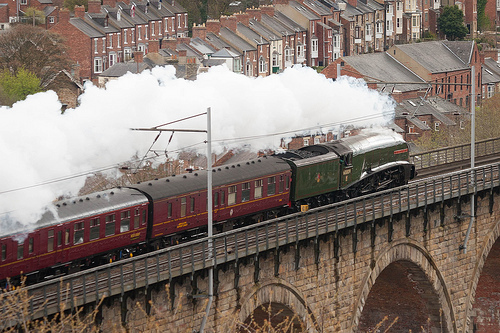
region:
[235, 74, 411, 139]
large section of white smoke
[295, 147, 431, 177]
green car on train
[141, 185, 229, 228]
tall windows on side of train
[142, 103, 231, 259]
tall silver pole on bridge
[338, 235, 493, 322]
large brick archway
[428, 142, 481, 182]
black train tracks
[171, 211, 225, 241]
yellow words on the side of train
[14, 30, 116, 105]
large over turned green tree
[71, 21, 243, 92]
large red apartment building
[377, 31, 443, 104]
gray roof on apartment building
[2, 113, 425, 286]
Green and red train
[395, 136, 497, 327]
Train bridge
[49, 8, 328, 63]
Housing overlooking the train bridge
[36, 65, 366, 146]
Steam from the train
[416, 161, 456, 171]
Train track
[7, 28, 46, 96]
Trees tucked beside the houses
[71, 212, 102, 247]
Train windows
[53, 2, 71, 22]
A brick chimney on the houses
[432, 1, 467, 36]
A healthy tree in front of the houses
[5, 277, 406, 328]
Weeds in the forground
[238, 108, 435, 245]
Green train engine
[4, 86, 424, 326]
Train with 3 cars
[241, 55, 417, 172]
smoke coming from train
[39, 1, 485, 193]
Many houses behind train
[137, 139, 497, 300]
Train going over bridge.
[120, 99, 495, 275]
Cables running by train tracks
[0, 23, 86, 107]
Trees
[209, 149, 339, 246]
Some train window shades are closed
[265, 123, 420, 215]
Coal inside train engine car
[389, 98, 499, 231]
Railings beside train tracks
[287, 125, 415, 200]
green train engine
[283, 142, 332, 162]
coal supply for train engine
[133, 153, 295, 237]
first dark red passenger car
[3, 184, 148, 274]
second dark red passenger car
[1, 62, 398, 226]
smoke from train locomotive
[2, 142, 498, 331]
railroad bridge over river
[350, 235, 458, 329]
brick arch of bridge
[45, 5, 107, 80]
brick rowhouse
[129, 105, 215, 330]
electrical pole attached to bridge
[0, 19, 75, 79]
tree just starting to leaf out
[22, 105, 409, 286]
train on the tracks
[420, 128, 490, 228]
tracks on a bridge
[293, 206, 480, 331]
bridge below tracks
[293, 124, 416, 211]
Green front of the train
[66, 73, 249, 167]
snow next to train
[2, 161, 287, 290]
windows on the train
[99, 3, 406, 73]
buildings next to train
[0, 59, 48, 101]
tree next to houses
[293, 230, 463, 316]
brown bridge below train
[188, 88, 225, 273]
Long silver pole next to train